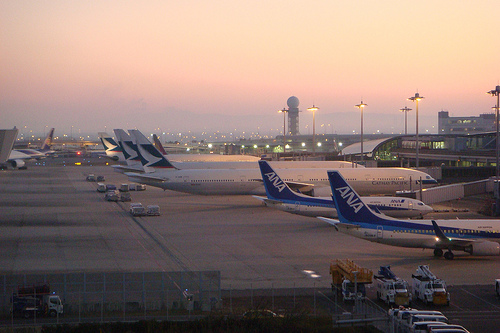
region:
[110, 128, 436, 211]
Two large airplanes parked by the terminal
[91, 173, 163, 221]
A collection of airport vehicles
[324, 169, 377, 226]
The blue tail of an airplane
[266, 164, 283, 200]
The letters ANA in white on blue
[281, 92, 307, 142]
Airport control tower with radar dish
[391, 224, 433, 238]
Series of aircraft windows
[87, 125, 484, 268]
planes at the airport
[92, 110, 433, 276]
planes at the airport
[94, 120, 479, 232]
planes at the airport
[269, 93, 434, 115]
the lights are illuminated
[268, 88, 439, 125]
the lights are illuminated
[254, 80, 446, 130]
the lights are illuminated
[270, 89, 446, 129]
the lights are illuminated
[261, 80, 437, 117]
the lights are illuminated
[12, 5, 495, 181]
Sky is cloudy and hazy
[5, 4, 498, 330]
Large airport with several planes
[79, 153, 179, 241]
Cargo vehicles stationed behind the planes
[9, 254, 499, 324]
Fence line seen in the foreground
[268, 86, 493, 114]
Tall light posts are on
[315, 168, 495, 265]
ANA written on the tail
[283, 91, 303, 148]
Round water reservoir seen in the distance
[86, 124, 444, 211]
Planes parked next to each other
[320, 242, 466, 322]
utility trucks seen in front of planes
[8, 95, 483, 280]
Passenger planes on the tarmac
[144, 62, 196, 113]
white clouds in blue sky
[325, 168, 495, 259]
blue and white plane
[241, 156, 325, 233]
blue and white tail of plane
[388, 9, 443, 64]
white clouds in blue sky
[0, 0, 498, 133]
pink sunset sky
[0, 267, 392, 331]
tall chain link fencing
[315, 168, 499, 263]
blue and white commercial airplane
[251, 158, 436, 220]
blue and white commercial airplane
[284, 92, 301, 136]
tall metal radar tower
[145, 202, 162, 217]
wrapped palette of luggage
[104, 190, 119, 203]
wrapped palette of luggage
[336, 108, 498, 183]
large airport terminal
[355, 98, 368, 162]
tall silver lamppost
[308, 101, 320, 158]
tall silver lamppost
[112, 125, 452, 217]
a big white commercial airplane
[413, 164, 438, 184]
the front window of a white airplane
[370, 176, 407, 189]
the logo of a white airplane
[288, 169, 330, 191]
the windows of a white airplane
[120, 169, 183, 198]
the back wings of a white airplane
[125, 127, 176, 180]
the tail fin of a white airplane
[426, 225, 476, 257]
the wings of a white airplane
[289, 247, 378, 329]
A white and yellow truck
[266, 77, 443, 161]
Light outside of the airport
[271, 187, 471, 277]
A plane with a blue tail